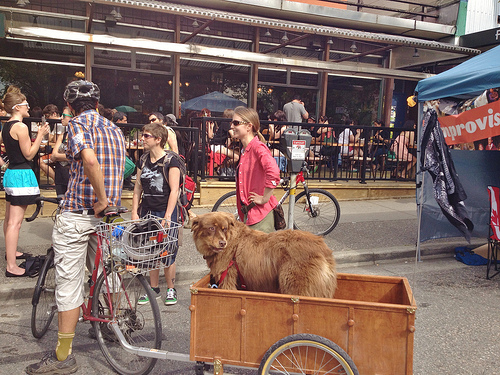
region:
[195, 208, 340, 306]
a large brown dog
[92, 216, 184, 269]
a large silver bike basket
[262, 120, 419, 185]
a large black rail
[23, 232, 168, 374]
a red bike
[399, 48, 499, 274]
part of a blue tent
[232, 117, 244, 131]
dark black sunglasses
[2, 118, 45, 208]
a woman's sleeveless dress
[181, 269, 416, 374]
a brown wooden wagon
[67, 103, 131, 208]
part of a colored shirt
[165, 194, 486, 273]
a concrete sidewalk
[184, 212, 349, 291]
dog in the wagon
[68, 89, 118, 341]
person on the bike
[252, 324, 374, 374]
bike on the wagon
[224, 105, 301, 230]
person standing on the street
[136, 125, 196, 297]
person standing on the street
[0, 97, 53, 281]
person standing on the street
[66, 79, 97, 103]
helmet on the head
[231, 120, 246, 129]
sunglasses on the person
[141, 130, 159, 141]
sunglasses on the person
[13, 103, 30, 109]
sunglasses on the person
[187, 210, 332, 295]
Brown dog in a cart on the street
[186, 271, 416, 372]
Brown, wooden cart carry a dog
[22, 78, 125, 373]
Young man on a bike attached to a cart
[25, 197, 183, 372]
Bicycle attached to a wooden cart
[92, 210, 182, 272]
Wire basket on back of a bicycle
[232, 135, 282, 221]
Hot pink sweater on woman on the street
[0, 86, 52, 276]
Woman standing on the sidewalk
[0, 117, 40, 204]
Black, blue, and white outfit on woman on sidewalk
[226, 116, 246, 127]
Sunglasses of lady on street in pink sweater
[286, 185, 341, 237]
Front tire of bicycle on sidewalk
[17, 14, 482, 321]
this photo is taken outside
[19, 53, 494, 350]
this setting is on a street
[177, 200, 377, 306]
this is a dog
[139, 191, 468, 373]
the dog is in a cart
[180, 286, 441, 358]
the cart is made of wood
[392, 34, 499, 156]
this is a tent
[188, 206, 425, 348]
the dog is light brown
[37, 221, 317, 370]
the cart is connected to a bike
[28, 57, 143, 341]
this is a cyclist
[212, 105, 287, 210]
this is a woman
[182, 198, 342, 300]
brown dog in back of wooden wagon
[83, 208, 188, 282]
metal basket on back of bicycle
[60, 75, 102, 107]
hard hat helmet on man riding bicycle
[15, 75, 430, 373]
man pulling dog behind him in a wooden wagon on a bicycle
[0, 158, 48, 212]
blue, white and black pair of shorts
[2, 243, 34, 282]
pair of black flats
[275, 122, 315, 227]
double black parking meter on metal pole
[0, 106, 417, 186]
long black metal fence in front of restaurant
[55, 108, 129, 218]
short sleeve blue, orange and white plaid shirt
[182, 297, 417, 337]
round knobs on side of wooden wagon